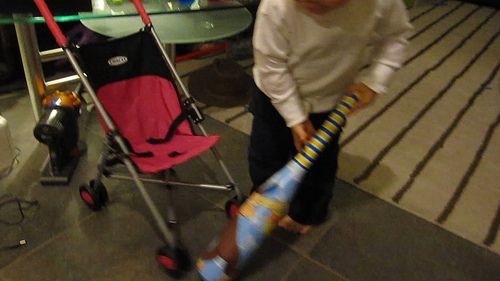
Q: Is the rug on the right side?
A: Yes, the rug is on the right of the image.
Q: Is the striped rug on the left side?
A: No, the rug is on the right of the image.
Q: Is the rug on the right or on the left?
A: The rug is on the right of the image.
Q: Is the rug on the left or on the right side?
A: The rug is on the right of the image.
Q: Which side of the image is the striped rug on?
A: The rug is on the right of the image.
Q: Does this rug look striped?
A: Yes, the rug is striped.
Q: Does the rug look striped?
A: Yes, the rug is striped.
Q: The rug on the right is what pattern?
A: The rug is striped.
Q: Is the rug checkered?
A: No, the rug is striped.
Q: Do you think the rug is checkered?
A: No, the rug is striped.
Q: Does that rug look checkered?
A: No, the rug is striped.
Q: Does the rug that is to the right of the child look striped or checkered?
A: The rug is striped.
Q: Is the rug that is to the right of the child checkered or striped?
A: The rug is striped.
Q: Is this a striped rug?
A: Yes, this is a striped rug.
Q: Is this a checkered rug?
A: No, this is a striped rug.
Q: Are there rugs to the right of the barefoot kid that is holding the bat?
A: Yes, there is a rug to the right of the kid.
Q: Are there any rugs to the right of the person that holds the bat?
A: Yes, there is a rug to the right of the kid.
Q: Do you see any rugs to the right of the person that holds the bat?
A: Yes, there is a rug to the right of the kid.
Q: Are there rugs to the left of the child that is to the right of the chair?
A: No, the rug is to the right of the child.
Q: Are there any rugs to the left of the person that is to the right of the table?
A: No, the rug is to the right of the child.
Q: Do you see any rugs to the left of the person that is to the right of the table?
A: No, the rug is to the right of the child.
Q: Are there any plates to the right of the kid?
A: No, there is a rug to the right of the kid.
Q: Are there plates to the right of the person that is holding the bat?
A: No, there is a rug to the right of the kid.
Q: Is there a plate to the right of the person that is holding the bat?
A: No, there is a rug to the right of the kid.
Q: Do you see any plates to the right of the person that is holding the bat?
A: No, there is a rug to the right of the kid.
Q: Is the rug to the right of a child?
A: Yes, the rug is to the right of a child.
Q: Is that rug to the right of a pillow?
A: No, the rug is to the right of a child.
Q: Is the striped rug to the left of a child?
A: No, the rug is to the right of a child.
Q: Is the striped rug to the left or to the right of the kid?
A: The rug is to the right of the kid.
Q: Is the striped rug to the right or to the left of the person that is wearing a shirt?
A: The rug is to the right of the kid.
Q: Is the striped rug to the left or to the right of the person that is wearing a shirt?
A: The rug is to the right of the kid.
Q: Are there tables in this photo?
A: Yes, there is a table.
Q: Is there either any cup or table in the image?
A: Yes, there is a table.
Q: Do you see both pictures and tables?
A: No, there is a table but no pictures.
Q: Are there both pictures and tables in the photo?
A: No, there is a table but no pictures.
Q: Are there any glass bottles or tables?
A: Yes, there is a glass table.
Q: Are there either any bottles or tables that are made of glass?
A: Yes, the table is made of glass.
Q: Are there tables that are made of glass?
A: Yes, there is a table that is made of glass.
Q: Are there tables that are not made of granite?
A: Yes, there is a table that is made of glass.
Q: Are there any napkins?
A: No, there are no napkins.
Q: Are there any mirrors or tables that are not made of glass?
A: No, there is a table but it is made of glass.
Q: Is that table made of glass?
A: Yes, the table is made of glass.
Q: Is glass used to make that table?
A: Yes, the table is made of glass.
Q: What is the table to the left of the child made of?
A: The table is made of glass.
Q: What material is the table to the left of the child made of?
A: The table is made of glass.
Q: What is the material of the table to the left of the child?
A: The table is made of glass.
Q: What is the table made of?
A: The table is made of glass.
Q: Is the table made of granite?
A: No, the table is made of glass.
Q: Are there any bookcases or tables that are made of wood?
A: No, there is a table but it is made of glass.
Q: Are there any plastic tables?
A: No, there is a table but it is made of glass.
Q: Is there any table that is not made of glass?
A: No, there is a table but it is made of glass.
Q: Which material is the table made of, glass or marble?
A: The table is made of glass.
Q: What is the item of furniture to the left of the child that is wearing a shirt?
A: The piece of furniture is a table.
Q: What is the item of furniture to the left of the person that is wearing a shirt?
A: The piece of furniture is a table.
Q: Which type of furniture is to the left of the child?
A: The piece of furniture is a table.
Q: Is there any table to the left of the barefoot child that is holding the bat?
A: Yes, there is a table to the left of the child.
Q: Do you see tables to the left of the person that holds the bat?
A: Yes, there is a table to the left of the child.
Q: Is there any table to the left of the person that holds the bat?
A: Yes, there is a table to the left of the child.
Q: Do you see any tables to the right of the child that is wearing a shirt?
A: No, the table is to the left of the child.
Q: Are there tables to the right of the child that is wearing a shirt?
A: No, the table is to the left of the child.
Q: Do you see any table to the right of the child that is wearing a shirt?
A: No, the table is to the left of the child.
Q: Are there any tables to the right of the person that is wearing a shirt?
A: No, the table is to the left of the child.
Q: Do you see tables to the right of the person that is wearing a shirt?
A: No, the table is to the left of the child.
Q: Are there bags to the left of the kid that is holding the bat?
A: No, there is a table to the left of the child.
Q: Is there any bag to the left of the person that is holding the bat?
A: No, there is a table to the left of the child.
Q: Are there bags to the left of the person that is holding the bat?
A: No, there is a table to the left of the child.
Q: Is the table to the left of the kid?
A: Yes, the table is to the left of the kid.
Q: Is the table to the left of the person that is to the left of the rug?
A: Yes, the table is to the left of the kid.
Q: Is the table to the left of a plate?
A: No, the table is to the left of the kid.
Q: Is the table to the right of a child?
A: No, the table is to the left of a child.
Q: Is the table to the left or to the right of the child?
A: The table is to the left of the child.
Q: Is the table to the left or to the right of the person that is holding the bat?
A: The table is to the left of the child.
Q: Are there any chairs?
A: Yes, there is a chair.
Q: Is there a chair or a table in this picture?
A: Yes, there is a chair.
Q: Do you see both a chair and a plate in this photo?
A: No, there is a chair but no plates.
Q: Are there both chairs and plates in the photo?
A: No, there is a chair but no plates.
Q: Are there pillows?
A: No, there are no pillows.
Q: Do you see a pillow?
A: No, there are no pillows.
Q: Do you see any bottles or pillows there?
A: No, there are no pillows or bottles.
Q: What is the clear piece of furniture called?
A: The piece of furniture is a chair.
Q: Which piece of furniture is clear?
A: The piece of furniture is a chair.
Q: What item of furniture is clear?
A: The piece of furniture is a chair.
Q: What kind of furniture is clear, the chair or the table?
A: The chair is clear.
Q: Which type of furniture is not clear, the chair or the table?
A: The table is not clear.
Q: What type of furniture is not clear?
A: The furniture is a table.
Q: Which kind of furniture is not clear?
A: The furniture is a table.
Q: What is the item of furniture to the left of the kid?
A: The piece of furniture is a chair.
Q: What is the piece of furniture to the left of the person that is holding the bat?
A: The piece of furniture is a chair.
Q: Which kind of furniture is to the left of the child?
A: The piece of furniture is a chair.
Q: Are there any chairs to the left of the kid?
A: Yes, there is a chair to the left of the kid.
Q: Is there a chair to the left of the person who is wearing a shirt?
A: Yes, there is a chair to the left of the kid.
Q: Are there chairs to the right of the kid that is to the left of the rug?
A: No, the chair is to the left of the kid.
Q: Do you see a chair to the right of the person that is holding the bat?
A: No, the chair is to the left of the kid.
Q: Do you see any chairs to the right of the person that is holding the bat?
A: No, the chair is to the left of the kid.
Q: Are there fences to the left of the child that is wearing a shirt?
A: No, there is a chair to the left of the child.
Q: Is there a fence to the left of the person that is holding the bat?
A: No, there is a chair to the left of the child.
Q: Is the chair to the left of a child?
A: Yes, the chair is to the left of a child.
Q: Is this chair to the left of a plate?
A: No, the chair is to the left of a child.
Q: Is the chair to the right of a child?
A: No, the chair is to the left of a child.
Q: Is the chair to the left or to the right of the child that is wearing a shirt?
A: The chair is to the left of the kid.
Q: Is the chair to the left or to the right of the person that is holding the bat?
A: The chair is to the left of the kid.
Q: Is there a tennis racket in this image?
A: No, there are no rackets.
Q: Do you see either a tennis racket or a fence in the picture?
A: No, there are no rackets or fences.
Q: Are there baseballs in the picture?
A: No, there are no baseballs.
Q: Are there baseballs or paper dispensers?
A: No, there are no baseballs or paper dispensers.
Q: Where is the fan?
A: The fan is on the floor.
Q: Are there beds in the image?
A: No, there are no beds.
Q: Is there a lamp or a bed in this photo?
A: No, there are no beds or lamps.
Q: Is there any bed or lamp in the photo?
A: No, there are no beds or lamps.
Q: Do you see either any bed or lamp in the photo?
A: No, there are no beds or lamps.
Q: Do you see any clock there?
A: No, there are no clocks.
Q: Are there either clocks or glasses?
A: No, there are no clocks or glasses.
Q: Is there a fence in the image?
A: No, there are no fences.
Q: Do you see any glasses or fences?
A: No, there are no fences or glasses.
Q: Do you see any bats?
A: Yes, there is a bat.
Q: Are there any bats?
A: Yes, there is a bat.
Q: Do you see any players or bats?
A: Yes, there is a bat.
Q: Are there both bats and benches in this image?
A: No, there is a bat but no benches.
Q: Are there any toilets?
A: No, there are no toilets.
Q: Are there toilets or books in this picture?
A: No, there are no toilets or books.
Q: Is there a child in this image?
A: Yes, there is a child.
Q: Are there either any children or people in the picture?
A: Yes, there is a child.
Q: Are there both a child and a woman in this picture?
A: No, there is a child but no women.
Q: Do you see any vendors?
A: No, there are no vendors.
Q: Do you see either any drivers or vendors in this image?
A: No, there are no vendors or drivers.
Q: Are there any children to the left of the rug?
A: Yes, there is a child to the left of the rug.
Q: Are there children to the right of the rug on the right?
A: No, the child is to the left of the rug.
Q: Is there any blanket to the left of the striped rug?
A: No, there is a child to the left of the rug.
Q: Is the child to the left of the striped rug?
A: Yes, the child is to the left of the rug.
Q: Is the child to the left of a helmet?
A: No, the child is to the left of the rug.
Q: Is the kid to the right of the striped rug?
A: No, the kid is to the left of the rug.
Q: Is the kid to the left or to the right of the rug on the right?
A: The kid is to the left of the rug.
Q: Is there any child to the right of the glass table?
A: Yes, there is a child to the right of the table.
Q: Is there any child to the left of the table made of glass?
A: No, the child is to the right of the table.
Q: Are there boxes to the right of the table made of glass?
A: No, there is a child to the right of the table.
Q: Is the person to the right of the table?
A: Yes, the child is to the right of the table.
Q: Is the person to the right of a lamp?
A: No, the child is to the right of the table.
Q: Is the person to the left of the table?
A: No, the child is to the right of the table.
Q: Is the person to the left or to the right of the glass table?
A: The child is to the right of the table.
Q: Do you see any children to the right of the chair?
A: Yes, there is a child to the right of the chair.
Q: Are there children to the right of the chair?
A: Yes, there is a child to the right of the chair.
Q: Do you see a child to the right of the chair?
A: Yes, there is a child to the right of the chair.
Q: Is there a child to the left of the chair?
A: No, the child is to the right of the chair.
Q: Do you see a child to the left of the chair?
A: No, the child is to the right of the chair.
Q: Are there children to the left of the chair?
A: No, the child is to the right of the chair.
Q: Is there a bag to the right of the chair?
A: No, there is a child to the right of the chair.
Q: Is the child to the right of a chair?
A: Yes, the child is to the right of a chair.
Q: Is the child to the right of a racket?
A: No, the child is to the right of a chair.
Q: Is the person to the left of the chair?
A: No, the kid is to the right of the chair.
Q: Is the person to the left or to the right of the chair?
A: The kid is to the right of the chair.